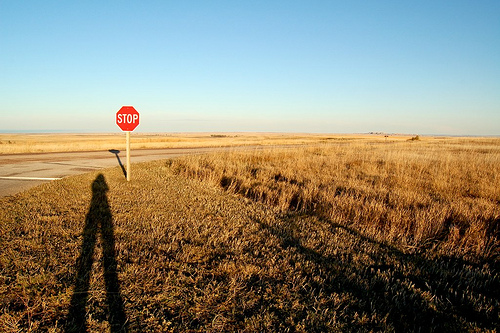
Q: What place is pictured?
A: It is a field.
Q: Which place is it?
A: It is a field.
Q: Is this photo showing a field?
A: Yes, it is showing a field.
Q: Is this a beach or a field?
A: It is a field.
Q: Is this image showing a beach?
A: No, the picture is showing a field.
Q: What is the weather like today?
A: It is cloudless.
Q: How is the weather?
A: It is cloudless.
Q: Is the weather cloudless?
A: Yes, it is cloudless.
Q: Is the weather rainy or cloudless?
A: It is cloudless.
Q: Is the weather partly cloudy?
A: No, it is cloudless.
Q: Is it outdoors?
A: Yes, it is outdoors.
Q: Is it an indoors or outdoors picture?
A: It is outdoors.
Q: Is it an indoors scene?
A: No, it is outdoors.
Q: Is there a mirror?
A: No, there are no mirrors.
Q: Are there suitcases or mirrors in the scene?
A: No, there are no mirrors or suitcases.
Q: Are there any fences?
A: No, there are no fences.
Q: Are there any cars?
A: No, there are no cars.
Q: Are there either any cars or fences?
A: No, there are no cars or fences.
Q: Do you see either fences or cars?
A: No, there are no cars or fences.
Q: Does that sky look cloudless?
A: Yes, the sky is cloudless.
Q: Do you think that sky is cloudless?
A: Yes, the sky is cloudless.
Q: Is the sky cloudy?
A: No, the sky is cloudless.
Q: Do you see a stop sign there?
A: Yes, there is a stop sign.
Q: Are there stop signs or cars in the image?
A: Yes, there is a stop sign.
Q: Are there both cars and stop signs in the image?
A: No, there is a stop sign but no cars.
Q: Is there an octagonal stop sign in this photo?
A: Yes, there is an octagonal stop sign.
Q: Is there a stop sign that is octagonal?
A: Yes, there is a stop sign that is octagonal.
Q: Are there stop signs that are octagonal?
A: Yes, there is a stop sign that is octagonal.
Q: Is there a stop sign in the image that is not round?
A: Yes, there is a octagonal stop sign.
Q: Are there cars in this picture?
A: No, there are no cars.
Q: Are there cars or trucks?
A: No, there are no cars or trucks.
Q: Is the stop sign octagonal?
A: Yes, the stop sign is octagonal.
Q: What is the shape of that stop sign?
A: The stop sign is octagonal.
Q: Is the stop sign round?
A: No, the stop sign is octagonal.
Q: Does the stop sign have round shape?
A: No, the stop sign is octagonal.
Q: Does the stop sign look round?
A: No, the stop sign is octagonal.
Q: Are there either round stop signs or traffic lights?
A: No, there is a stop sign but it is octagonal.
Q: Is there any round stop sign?
A: No, there is a stop sign but it is octagonal.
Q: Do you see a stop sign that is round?
A: No, there is a stop sign but it is octagonal.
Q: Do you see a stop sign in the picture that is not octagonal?
A: No, there is a stop sign but it is octagonal.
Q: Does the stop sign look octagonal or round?
A: The stop sign is octagonal.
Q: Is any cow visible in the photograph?
A: No, there are no cows.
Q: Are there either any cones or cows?
A: No, there are no cows or cones.